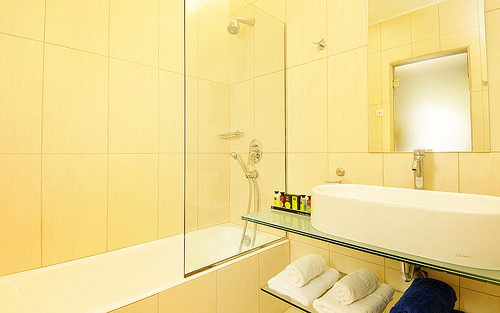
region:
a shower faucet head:
[227, 16, 257, 35]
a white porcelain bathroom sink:
[312, 179, 499, 273]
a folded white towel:
[284, 252, 325, 287]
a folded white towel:
[331, 265, 379, 304]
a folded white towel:
[265, 253, 339, 306]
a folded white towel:
[313, 269, 393, 311]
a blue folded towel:
[388, 275, 458, 312]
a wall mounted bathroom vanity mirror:
[367, 0, 492, 154]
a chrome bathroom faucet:
[412, 149, 425, 188]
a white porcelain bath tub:
[1, 221, 283, 311]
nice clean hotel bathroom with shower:
[50, 14, 474, 300]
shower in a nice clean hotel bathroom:
[190, 5, 294, 250]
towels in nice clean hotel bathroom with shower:
[280, 248, 377, 307]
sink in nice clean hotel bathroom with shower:
[312, 166, 486, 261]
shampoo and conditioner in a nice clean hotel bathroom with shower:
[274, 191, 317, 218]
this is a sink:
[321, 174, 476, 249]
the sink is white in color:
[338, 183, 394, 235]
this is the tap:
[403, 150, 428, 181]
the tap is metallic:
[403, 147, 428, 189]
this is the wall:
[44, 50, 126, 173]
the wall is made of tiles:
[28, 26, 126, 146]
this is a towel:
[283, 251, 319, 296]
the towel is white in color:
[284, 261, 341, 297]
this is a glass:
[204, 11, 265, 123]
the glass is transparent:
[200, 37, 276, 171]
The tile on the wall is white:
[28, 48, 151, 218]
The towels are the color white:
[273, 248, 340, 305]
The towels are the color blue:
[383, 280, 466, 311]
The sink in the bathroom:
[304, 176, 498, 272]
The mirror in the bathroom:
[355, 5, 496, 162]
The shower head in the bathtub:
[218, 10, 263, 38]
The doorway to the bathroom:
[376, 40, 485, 160]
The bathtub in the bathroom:
[0, 210, 302, 310]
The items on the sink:
[267, 185, 317, 217]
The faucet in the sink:
[408, 145, 426, 188]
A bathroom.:
[3, 3, 496, 308]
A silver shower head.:
[227, 15, 256, 35]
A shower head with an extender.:
[227, 146, 261, 251]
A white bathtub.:
[1, 220, 281, 311]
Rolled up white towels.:
[286, 254, 373, 301]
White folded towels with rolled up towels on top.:
[268, 252, 403, 312]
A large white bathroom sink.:
[305, 179, 499, 272]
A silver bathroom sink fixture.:
[406, 148, 427, 187]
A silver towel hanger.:
[308, 38, 328, 50]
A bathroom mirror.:
[366, 4, 498, 153]